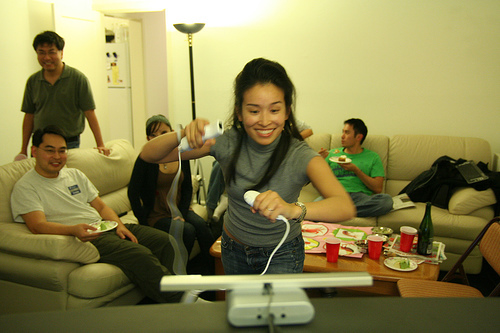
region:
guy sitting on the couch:
[0, 126, 135, 321]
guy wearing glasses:
[11, 126, 131, 296]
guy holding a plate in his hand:
[20, 125, 126, 300]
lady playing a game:
[165, 57, 336, 302]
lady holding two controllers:
[162, 50, 352, 300]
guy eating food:
[306, 96, 401, 217]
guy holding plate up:
[311, 101, 402, 211]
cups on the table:
[310, 205, 421, 275]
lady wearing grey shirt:
[145, 40, 355, 280]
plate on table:
[378, 252, 462, 287]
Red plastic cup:
[315, 235, 345, 270]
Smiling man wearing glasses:
[30, 125, 70, 190]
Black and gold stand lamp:
[170, 10, 205, 115]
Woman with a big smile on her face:
[230, 55, 295, 155]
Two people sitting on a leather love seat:
[5, 110, 180, 305]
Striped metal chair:
[405, 220, 495, 290]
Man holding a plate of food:
[315, 110, 385, 180]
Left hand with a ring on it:
[245, 190, 285, 230]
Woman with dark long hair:
[224, 51, 300, 191]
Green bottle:
[413, 200, 439, 281]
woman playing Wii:
[139, 42, 385, 312]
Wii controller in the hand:
[154, 105, 236, 164]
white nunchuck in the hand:
[232, 167, 304, 229]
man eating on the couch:
[315, 114, 396, 223]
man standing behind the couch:
[14, 22, 117, 177]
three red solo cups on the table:
[319, 227, 443, 269]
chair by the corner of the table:
[379, 227, 499, 315]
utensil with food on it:
[319, 137, 341, 157]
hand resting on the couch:
[96, 140, 121, 163]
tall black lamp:
[168, 17, 224, 122]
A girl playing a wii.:
[136, 54, 366, 304]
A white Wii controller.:
[169, 117, 226, 149]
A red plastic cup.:
[323, 224, 420, 265]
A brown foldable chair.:
[391, 215, 498, 295]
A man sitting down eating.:
[321, 115, 399, 219]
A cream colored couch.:
[224, 131, 494, 279]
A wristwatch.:
[289, 197, 308, 227]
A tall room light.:
[171, 16, 214, 168]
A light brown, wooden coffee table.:
[209, 202, 443, 290]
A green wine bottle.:
[416, 202, 438, 255]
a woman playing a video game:
[140, 54, 365, 275]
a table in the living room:
[293, 215, 438, 299]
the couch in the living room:
[284, 124, 489, 272]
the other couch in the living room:
[0, 146, 190, 303]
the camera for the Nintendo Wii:
[150, 267, 384, 319]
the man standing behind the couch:
[9, 23, 114, 160]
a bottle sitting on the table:
[418, 194, 435, 262]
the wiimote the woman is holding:
[174, 117, 293, 274]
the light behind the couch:
[165, 23, 212, 126]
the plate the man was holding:
[77, 208, 116, 243]